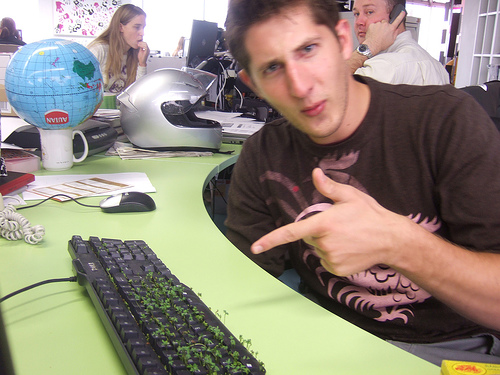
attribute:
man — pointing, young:
[217, 2, 500, 368]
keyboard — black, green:
[63, 235, 263, 375]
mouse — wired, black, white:
[100, 190, 156, 213]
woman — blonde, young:
[85, 7, 147, 103]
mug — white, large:
[38, 127, 90, 172]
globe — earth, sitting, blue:
[3, 40, 108, 126]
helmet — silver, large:
[111, 63, 228, 154]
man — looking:
[348, 1, 450, 88]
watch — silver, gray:
[355, 42, 372, 58]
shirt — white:
[353, 30, 447, 87]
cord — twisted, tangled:
[3, 193, 48, 245]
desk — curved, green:
[3, 53, 444, 370]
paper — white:
[21, 169, 157, 205]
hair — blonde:
[88, 8, 142, 81]